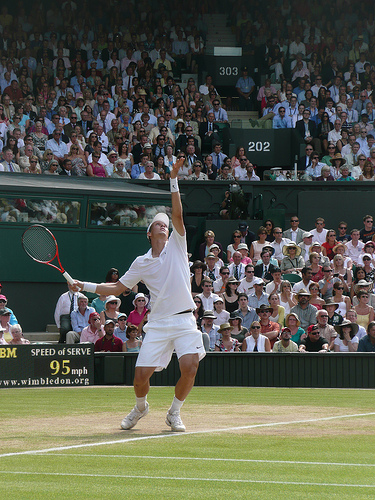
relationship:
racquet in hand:
[14, 210, 84, 292] [50, 271, 99, 308]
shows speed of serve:
[48, 358, 87, 379] [156, 153, 201, 217]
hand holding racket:
[50, 271, 99, 308] [14, 210, 84, 292]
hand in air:
[50, 271, 99, 308] [120, 114, 215, 163]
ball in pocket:
[129, 319, 158, 337] [134, 327, 167, 350]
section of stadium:
[254, 11, 373, 132] [6, 8, 361, 139]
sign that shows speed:
[25, 340, 113, 382] [40, 356, 99, 380]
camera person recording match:
[217, 182, 281, 222] [36, 66, 350, 406]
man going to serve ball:
[93, 163, 201, 429] [120, 119, 241, 276]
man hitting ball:
[93, 142, 235, 428] [129, 319, 158, 337]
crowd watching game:
[6, 8, 361, 139] [29, 233, 315, 497]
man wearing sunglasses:
[244, 263, 265, 287] [244, 267, 260, 277]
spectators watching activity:
[7, 16, 236, 161] [32, 47, 366, 218]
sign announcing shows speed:
[25, 340, 113, 382] [48, 358, 87, 379]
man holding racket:
[93, 142, 235, 428] [14, 210, 84, 292]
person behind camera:
[218, 156, 235, 181] [229, 186, 258, 215]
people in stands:
[11, 17, 374, 213] [2, 5, 368, 385]